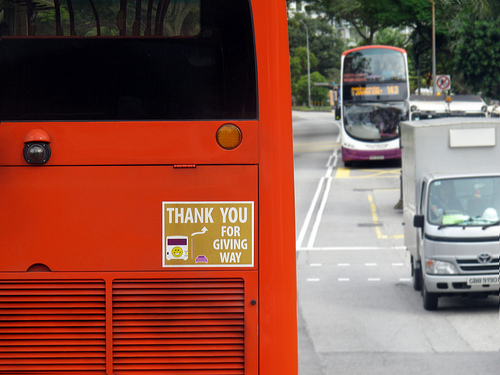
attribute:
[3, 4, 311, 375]
bus — orange, red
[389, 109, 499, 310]
truck — silver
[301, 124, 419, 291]
lines — white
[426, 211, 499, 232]
wipers — black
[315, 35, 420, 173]
bus — orange, white, double decker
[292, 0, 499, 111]
trees — green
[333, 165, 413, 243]
lines — yellow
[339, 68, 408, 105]
light — yellow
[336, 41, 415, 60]
roof — red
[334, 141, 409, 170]
bumper — purple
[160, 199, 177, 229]
t — written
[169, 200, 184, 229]
h — written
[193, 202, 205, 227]
n — written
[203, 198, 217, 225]
k — written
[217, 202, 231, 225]
y — written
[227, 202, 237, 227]
o — written